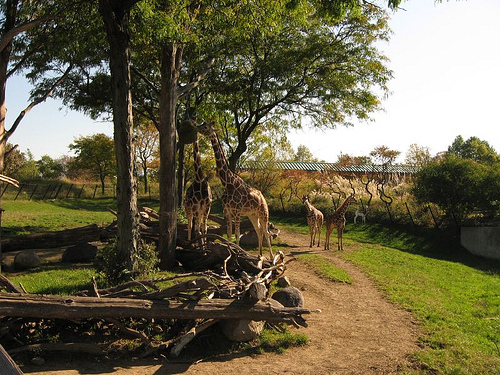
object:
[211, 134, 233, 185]
neck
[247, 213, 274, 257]
leg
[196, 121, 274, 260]
body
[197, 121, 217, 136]
head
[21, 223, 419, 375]
path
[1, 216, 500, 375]
ground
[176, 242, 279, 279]
log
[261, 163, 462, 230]
fence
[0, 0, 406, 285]
tree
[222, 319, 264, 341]
rock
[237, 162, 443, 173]
roof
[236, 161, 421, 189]
building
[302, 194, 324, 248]
baby